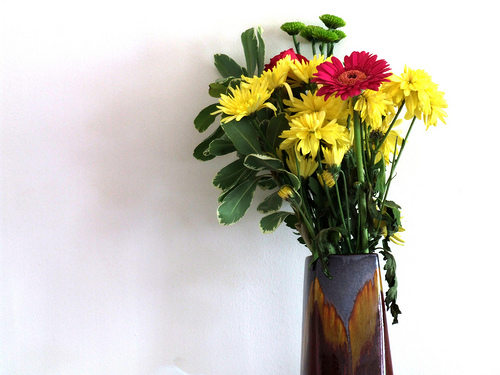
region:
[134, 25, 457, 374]
flowers in a ceramic vase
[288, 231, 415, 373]
vase is grey, orange, and red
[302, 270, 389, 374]
orange and red design on vase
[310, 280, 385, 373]
design on vase makes V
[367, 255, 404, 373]
light reflecting on vase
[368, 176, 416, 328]
leaves from flowers hanging over vase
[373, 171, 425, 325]
leaves are starting to wilt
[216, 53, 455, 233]
flowers are yellow and pink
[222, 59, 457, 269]
yellow and pink daisies in vase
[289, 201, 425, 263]
stems from flowers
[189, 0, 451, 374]
the flowers are yellow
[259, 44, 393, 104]
the flowers are pink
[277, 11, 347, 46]
the flowers are green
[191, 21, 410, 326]
flower leaves in the vase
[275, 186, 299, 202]
flower is not fully grown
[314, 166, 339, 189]
flower is not fully grown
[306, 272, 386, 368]
brown color on vase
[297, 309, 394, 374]
purple color on vase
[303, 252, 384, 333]
blue color on vase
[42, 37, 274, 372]
shadow of flowers on wall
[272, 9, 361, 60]
a few green flowers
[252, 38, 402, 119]
two red flowers in vase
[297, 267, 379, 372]
a dark brown and light brown vase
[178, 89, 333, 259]
large green and white leaves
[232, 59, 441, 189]
several yellow flowers in vase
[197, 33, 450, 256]
two red flowers with yellow flowers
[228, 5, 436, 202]
red, yellow and green flowers together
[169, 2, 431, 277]
a bouquet of red and yellow flowers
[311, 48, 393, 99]
Dark pink daisy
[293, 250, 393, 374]
Ceramic vase with flower petal painting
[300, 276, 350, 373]
Burgundy and yellow flower petal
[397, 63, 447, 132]
Flower with yellow petals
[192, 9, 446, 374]
Bouquet of flowers in a vase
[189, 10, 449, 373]
Flowers in a ceramic vase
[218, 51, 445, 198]
Yellow color daisies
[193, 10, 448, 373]
Bouquet of flowers in a painted vase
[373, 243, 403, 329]
Whittled leaf hanging from a bouquet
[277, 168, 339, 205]
Yellow flowers not fully bloomed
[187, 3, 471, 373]
flowers in a vase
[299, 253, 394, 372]
vase with flowers inside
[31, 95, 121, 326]
white wall behind flower vase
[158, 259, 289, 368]
shadow on a wall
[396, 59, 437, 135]
yellow flower in vase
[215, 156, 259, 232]
leaves of the flowers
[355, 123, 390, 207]
stems on a flower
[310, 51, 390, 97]
pink flower in a vases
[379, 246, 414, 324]
dead leaf in a vase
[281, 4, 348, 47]
green flowers in a vase